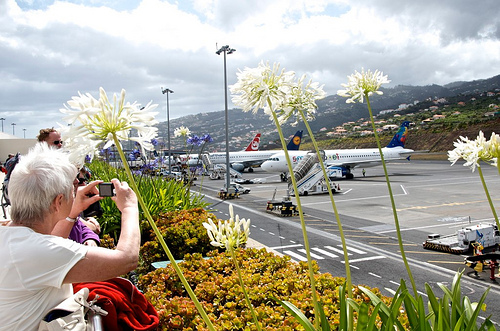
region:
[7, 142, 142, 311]
elderly person taking a photograph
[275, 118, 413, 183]
white airplane with blue tail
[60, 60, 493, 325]
tall white flowers in the foreground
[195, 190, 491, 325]
white paint on grey asphalt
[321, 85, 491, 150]
several houses on a hill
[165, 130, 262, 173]
white plane with red tail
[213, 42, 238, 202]
tall metal light post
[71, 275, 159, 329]
red jacket draped over a wall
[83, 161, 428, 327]
flower bed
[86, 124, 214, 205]
blue flowers with green stems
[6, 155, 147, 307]
The person is taking a picture with cellphone.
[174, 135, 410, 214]
Airplanes parked on the runway.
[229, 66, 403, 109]
The flowers are white.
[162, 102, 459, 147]
Houses on top of the mountains.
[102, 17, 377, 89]
The sky is dark and cloudy.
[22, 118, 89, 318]
People standing around and watching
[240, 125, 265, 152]
The tail of the plane is red and white.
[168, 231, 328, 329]
The flowers is in front of the lady.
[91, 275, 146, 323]
A red jacket hanging on the railing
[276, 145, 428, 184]
The plane is white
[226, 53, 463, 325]
White flowers in a bush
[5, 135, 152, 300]
Person taking a picture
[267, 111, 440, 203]
Airplane at an airport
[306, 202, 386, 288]
White and yellow lines on a road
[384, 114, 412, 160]
Blue tail on a plane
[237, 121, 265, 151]
Red tail on a plane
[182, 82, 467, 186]
Hill next to an airport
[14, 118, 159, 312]
People watching planes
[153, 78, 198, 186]
Light pole at an airport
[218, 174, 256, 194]
Car on a tarmac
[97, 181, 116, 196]
small camera phone in a persons hand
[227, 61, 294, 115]
large white flower on a stalk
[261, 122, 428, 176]
large white metal airplane on a runways with a blue tail wing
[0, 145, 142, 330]
older person with white hair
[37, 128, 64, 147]
mans head wearing black sunglases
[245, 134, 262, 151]
red tail of an airplane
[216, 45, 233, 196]
large tall metal pole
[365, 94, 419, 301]
long green flower stalk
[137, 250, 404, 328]
many small bush like flowers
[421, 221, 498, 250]
large white truck on a runway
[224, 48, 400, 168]
White flowers on the road.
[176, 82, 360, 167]
Mountains in the distance.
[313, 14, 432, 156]
Clouds in the sky.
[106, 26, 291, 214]
Lights on the road.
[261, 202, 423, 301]
White marks on the ground.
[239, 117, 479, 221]
Plane on the runway.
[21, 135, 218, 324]
Man with white hair.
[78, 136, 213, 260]
Camera in man's hand.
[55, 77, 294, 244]
White petals on the flower.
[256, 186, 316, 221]
Cart on the tarmac.